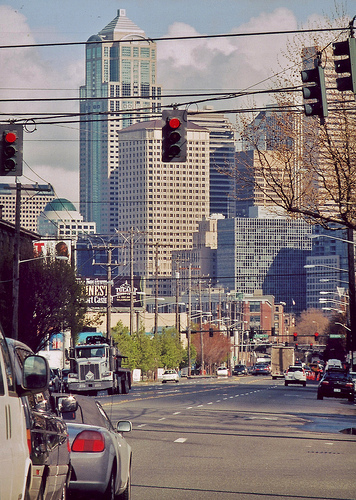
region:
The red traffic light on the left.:
[1, 128, 21, 145]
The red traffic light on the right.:
[164, 115, 183, 129]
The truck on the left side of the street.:
[50, 329, 130, 392]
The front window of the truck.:
[73, 348, 108, 357]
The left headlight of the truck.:
[64, 370, 76, 378]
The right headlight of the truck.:
[101, 370, 110, 376]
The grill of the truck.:
[78, 361, 101, 379]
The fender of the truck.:
[64, 382, 117, 390]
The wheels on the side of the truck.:
[112, 368, 131, 396]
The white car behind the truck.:
[156, 362, 180, 385]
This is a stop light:
[141, 109, 213, 216]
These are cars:
[39, 383, 123, 489]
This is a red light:
[163, 97, 193, 167]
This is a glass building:
[89, 143, 102, 190]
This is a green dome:
[32, 185, 109, 260]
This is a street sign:
[322, 314, 349, 352]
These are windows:
[102, 133, 188, 213]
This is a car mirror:
[18, 344, 48, 376]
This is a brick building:
[222, 291, 319, 367]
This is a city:
[126, 166, 318, 333]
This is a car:
[43, 400, 155, 498]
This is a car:
[280, 359, 312, 399]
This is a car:
[311, 354, 355, 412]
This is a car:
[154, 363, 183, 400]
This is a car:
[215, 359, 230, 384]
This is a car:
[268, 364, 287, 386]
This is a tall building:
[209, 204, 321, 339]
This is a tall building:
[115, 108, 227, 339]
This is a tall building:
[71, 6, 169, 310]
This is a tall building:
[35, 195, 99, 316]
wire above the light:
[177, 20, 242, 88]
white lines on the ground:
[160, 390, 211, 442]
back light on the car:
[70, 417, 111, 464]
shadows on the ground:
[212, 396, 267, 459]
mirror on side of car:
[115, 412, 136, 437]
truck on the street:
[61, 334, 131, 394]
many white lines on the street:
[195, 385, 268, 430]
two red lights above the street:
[285, 324, 324, 343]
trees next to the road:
[121, 325, 197, 365]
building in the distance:
[86, 8, 167, 93]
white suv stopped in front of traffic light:
[282, 327, 322, 388]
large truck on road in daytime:
[72, 337, 150, 394]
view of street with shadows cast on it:
[167, 388, 306, 479]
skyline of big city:
[86, 99, 298, 244]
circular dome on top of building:
[36, 198, 82, 238]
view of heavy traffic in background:
[230, 349, 316, 388]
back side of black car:
[320, 371, 354, 410]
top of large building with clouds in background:
[75, 6, 197, 82]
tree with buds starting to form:
[244, 117, 335, 204]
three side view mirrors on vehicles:
[20, 353, 134, 440]